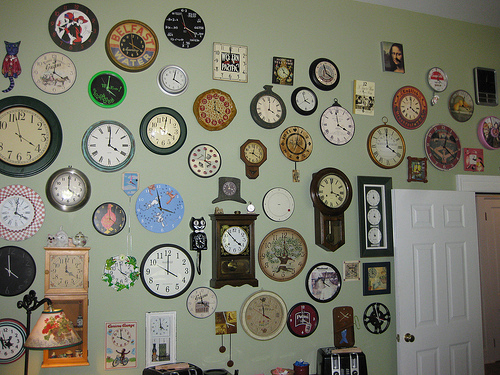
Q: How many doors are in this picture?
A: One.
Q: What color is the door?
A: White.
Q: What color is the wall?
A: Green.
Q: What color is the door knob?
A: Silver.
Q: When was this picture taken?
A: Four o'clock.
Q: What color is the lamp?
A: Black.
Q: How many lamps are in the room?
A: One.